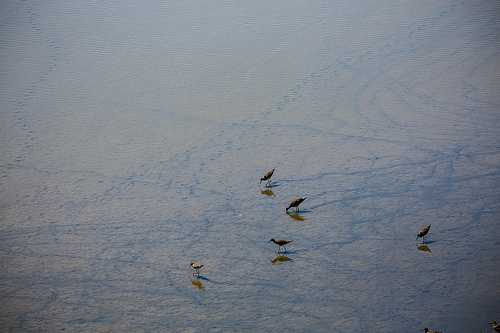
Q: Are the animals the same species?
A: Yes, all the animals are birds.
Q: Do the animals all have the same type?
A: Yes, all the animals are birds.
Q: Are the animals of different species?
A: No, all the animals are birds.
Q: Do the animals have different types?
A: No, all the animals are birds.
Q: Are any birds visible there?
A: Yes, there is a bird.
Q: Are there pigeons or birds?
A: Yes, there is a bird.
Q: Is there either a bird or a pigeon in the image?
A: Yes, there is a bird.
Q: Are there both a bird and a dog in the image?
A: No, there is a bird but no dogs.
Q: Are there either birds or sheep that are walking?
A: Yes, the bird is walking.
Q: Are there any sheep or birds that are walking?
A: Yes, the bird is walking.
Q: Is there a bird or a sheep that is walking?
A: Yes, the bird is walking.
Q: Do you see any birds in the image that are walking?
A: Yes, there is a bird that is walking.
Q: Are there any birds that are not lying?
A: Yes, there is a bird that is walking.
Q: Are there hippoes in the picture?
A: No, there are no hippoes.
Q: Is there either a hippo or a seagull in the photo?
A: No, there are no hippoes or seagulls.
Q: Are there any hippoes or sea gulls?
A: No, there are no hippoes or sea gulls.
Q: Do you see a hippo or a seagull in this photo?
A: No, there are no hippoes or seagulls.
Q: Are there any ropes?
A: No, there are no ropes.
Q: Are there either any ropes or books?
A: No, there are no ropes or books.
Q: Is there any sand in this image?
A: Yes, there is sand.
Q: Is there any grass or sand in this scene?
A: Yes, there is sand.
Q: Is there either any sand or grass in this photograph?
A: Yes, there is sand.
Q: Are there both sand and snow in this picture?
A: No, there is sand but no snow.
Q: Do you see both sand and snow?
A: No, there is sand but no snow.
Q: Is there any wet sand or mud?
A: Yes, there is wet sand.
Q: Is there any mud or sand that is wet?
A: Yes, the sand is wet.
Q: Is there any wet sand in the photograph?
A: Yes, there is wet sand.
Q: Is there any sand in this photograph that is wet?
A: Yes, there is sand that is wet.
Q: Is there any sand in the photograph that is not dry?
A: Yes, there is wet sand.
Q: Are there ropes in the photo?
A: No, there are no ropes.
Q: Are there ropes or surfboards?
A: No, there are no ropes or surfboards.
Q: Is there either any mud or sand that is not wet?
A: No, there is sand but it is wet.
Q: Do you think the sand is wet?
A: Yes, the sand is wet.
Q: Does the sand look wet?
A: Yes, the sand is wet.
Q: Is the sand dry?
A: No, the sand is wet.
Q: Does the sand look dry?
A: No, the sand is wet.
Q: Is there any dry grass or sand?
A: No, there is sand but it is wet.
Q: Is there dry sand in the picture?
A: No, there is sand but it is wet.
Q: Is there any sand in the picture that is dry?
A: No, there is sand but it is wet.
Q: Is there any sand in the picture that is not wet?
A: No, there is sand but it is wet.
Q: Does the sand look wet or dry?
A: The sand is wet.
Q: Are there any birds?
A: Yes, there is a bird.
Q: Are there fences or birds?
A: Yes, there is a bird.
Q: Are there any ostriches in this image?
A: No, there are no ostriches.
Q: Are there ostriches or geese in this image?
A: No, there are no ostriches or geese.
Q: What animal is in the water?
A: The bird is in the water.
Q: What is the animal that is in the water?
A: The animal is a bird.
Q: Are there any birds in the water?
A: Yes, there is a bird in the water.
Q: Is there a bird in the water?
A: Yes, there is a bird in the water.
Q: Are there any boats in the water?
A: No, there is a bird in the water.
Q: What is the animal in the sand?
A: The animal is a bird.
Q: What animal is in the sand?
A: The animal is a bird.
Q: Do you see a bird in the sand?
A: Yes, there is a bird in the sand.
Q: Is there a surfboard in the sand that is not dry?
A: No, there is a bird in the sand.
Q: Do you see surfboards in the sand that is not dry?
A: No, there is a bird in the sand.